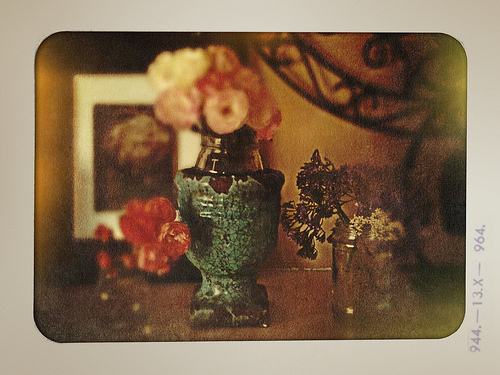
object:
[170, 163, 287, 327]
vase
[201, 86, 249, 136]
flower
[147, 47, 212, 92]
flower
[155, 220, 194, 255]
red flowers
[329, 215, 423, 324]
vase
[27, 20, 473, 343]
life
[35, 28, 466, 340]
still life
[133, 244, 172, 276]
flower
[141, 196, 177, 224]
flower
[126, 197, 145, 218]
flower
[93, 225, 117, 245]
flower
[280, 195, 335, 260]
flower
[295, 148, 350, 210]
flower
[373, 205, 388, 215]
flower